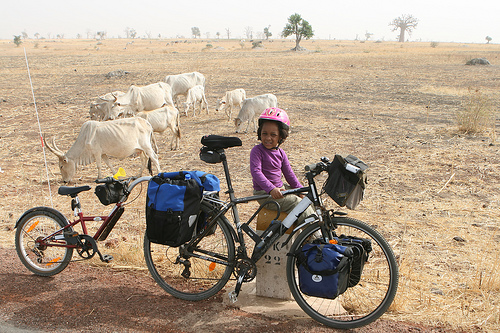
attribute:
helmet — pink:
[254, 103, 298, 133]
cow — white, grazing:
[225, 91, 288, 135]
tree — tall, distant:
[277, 4, 321, 55]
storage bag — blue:
[141, 167, 224, 246]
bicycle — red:
[143, 118, 405, 332]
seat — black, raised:
[192, 129, 246, 168]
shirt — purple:
[242, 144, 309, 189]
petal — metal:
[221, 289, 244, 305]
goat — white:
[173, 85, 214, 121]